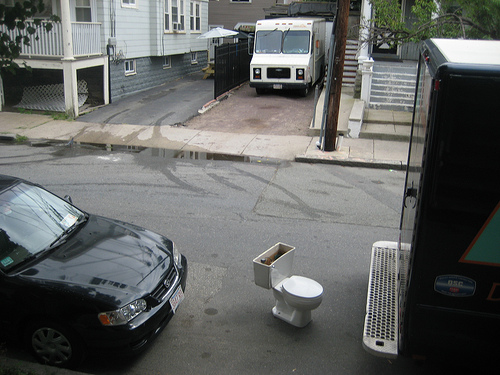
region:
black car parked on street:
[3, 177, 204, 364]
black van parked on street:
[399, 40, 498, 308]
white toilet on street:
[231, 237, 324, 333]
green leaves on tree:
[5, 5, 51, 61]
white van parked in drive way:
[245, 11, 319, 91]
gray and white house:
[64, 7, 209, 87]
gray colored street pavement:
[94, 161, 314, 216]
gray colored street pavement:
[276, 171, 384, 221]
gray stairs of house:
[365, 56, 407, 104]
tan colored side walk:
[62, 124, 219, 153]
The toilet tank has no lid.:
[245, 230, 298, 290]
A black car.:
[0, 160, 200, 366]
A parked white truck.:
[240, 15, 321, 110]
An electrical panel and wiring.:
[100, 31, 126, 67]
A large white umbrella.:
[195, 24, 243, 45]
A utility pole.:
[310, 0, 352, 151]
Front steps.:
[370, 61, 415, 116]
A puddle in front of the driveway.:
[80, 140, 242, 167]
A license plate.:
[164, 280, 193, 321]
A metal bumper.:
[356, 230, 403, 358]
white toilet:
[245, 235, 325, 331]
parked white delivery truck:
[240, 5, 330, 95]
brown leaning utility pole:
[316, 0, 346, 145]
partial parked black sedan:
[0, 160, 185, 370]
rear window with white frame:
[186, 0, 201, 32]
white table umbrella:
[190, 21, 235, 76]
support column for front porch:
[52, 0, 72, 60]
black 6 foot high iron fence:
[210, 40, 250, 95]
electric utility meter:
[102, 32, 122, 62]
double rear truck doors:
[387, 40, 442, 355]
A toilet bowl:
[219, 230, 288, 358]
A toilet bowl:
[256, 210, 335, 371]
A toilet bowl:
[294, 171, 347, 348]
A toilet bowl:
[257, 230, 311, 355]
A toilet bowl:
[247, 259, 284, 372]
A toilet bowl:
[242, 234, 313, 345]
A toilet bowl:
[292, 207, 357, 343]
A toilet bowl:
[300, 190, 356, 362]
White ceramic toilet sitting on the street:
[247, 232, 326, 341]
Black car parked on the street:
[0, 166, 193, 365]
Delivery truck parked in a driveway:
[248, 12, 328, 116]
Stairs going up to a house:
[366, 9, 416, 141]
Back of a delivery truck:
[360, 29, 482, 366]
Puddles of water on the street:
[34, 127, 225, 194]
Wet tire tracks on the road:
[20, 122, 336, 237]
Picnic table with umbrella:
[197, 20, 237, 94]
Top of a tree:
[367, 2, 496, 46]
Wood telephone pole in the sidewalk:
[310, 0, 362, 160]